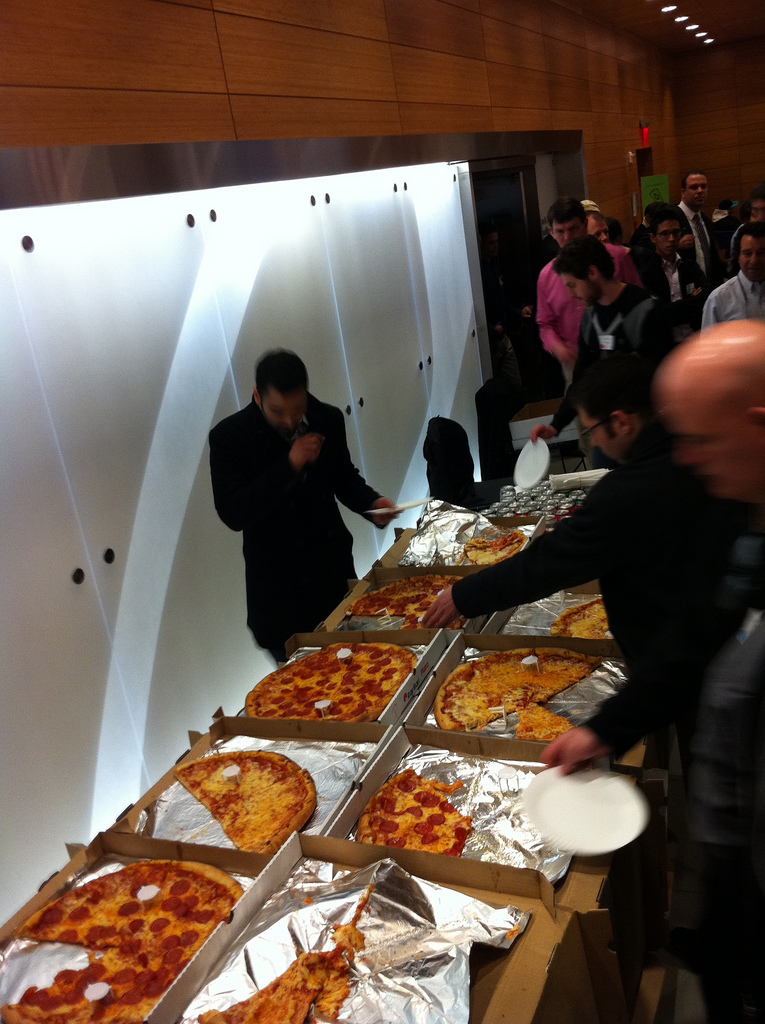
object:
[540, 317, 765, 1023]
bald man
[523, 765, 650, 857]
paper plate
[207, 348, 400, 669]
man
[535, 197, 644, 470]
man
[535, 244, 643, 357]
pink shirt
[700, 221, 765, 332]
people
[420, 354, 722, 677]
man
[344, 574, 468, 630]
pizza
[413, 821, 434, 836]
pepperoni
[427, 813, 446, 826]
pepperoni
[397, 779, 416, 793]
pepperoni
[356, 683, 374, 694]
pepperoni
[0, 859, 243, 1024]
pizza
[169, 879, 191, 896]
pepperoni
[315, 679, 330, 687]
pepperoni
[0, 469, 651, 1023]
table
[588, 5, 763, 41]
ceiling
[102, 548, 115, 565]
knobs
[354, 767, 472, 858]
pizza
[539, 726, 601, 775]
hand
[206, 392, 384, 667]
suit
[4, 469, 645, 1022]
buffet line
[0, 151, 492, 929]
wall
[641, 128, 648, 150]
red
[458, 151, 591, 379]
door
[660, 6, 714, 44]
five lights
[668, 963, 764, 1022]
hall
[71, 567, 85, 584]
knobs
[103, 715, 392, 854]
box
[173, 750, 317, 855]
half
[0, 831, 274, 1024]
box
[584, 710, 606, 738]
held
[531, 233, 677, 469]
person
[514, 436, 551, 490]
plate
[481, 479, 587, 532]
group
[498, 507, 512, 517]
cans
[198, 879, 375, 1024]
only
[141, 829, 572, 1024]
box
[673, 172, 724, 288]
man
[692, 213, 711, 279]
necktie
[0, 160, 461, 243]
lighting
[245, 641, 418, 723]
pizza